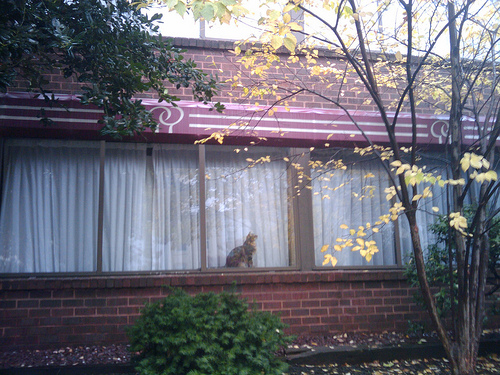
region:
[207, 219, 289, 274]
cat in the window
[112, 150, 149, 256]
white curtains on the window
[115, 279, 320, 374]
green bush in front of the building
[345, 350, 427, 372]
leaves on the ground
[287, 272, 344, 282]
brick border under the windows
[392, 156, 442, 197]
leaves in the bare tree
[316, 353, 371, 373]
sidewalk near the bush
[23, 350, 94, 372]
leaves littering the sidewalk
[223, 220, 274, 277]
cat looking up at the window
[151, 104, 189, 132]
design on the roof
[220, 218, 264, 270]
Cat sitting on a window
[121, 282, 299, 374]
Thick green plant at the wall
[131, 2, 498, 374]
Tree with yellowing leaves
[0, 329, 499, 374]
Ground littered with dry leaves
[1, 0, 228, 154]
Green leaves of a tree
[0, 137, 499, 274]
Long line of glass windows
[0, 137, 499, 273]
Window with white curtains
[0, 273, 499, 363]
Lower wall made of red bricks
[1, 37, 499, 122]
Upper wall of red bricks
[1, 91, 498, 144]
Long stripes of white lines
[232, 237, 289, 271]
a cat that is inside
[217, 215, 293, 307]
a cat sitting inside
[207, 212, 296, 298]
a cat sitting in a window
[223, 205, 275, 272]
a cat in a window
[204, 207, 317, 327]
curtains in a window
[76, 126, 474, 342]
a white curtains in the window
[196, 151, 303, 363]
curtains behind a cat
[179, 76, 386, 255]
a building with windows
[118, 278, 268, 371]
a bush with leaves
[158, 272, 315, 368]
a bush with green leaves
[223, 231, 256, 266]
A cat on the window sill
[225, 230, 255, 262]
A cat behind a window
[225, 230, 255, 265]
A cat in front of the curtain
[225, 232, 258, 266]
A cat between a curtain and a window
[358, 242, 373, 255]
Yellow leaves on a branch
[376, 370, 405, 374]
Leaves on the ground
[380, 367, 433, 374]
Dry leaves on the ground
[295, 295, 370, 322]
Bricks on a wall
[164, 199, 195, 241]
Reflection of leaves on the window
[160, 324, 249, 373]
A green plant on the ground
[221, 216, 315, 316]
a cat in a window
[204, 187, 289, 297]
a cat that is inside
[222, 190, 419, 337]
a cat sitting inside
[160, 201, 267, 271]
a cat sitting in a window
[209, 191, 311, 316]
a cat that is sitting inside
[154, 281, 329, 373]
a bush with leaves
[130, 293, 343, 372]
leaves on a bush